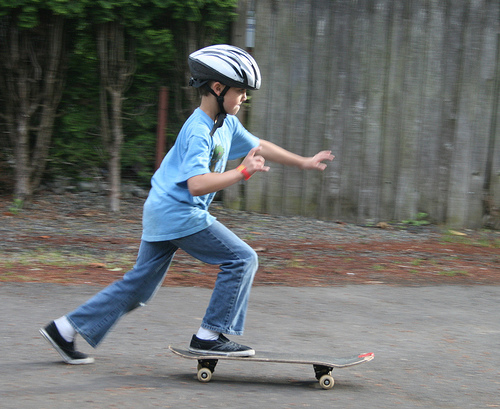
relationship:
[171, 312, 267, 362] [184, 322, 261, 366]
foot on skateboard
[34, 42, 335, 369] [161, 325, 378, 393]
boy riding skateboard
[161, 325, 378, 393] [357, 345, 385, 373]
skateboard has red tip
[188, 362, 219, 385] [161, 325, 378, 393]
wheel on skateboard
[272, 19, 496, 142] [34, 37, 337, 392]
fence behind boy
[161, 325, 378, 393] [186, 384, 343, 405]
skateboard on pavement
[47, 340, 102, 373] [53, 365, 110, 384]
foot touching pavement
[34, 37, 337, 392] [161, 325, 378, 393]
boy on skateboard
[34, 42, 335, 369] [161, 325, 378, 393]
boy on skateboard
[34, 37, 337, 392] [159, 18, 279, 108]
boy wearing helmet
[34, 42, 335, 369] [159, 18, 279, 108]
boy wearing helmet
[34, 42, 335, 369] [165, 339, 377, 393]
boy on skateboard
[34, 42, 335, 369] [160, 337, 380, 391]
boy on skateboard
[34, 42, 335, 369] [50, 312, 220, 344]
boy wears socks